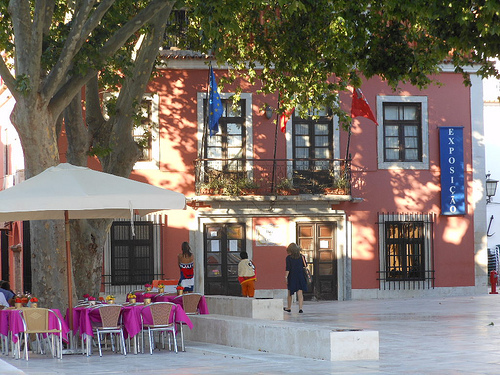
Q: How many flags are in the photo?
A: Three.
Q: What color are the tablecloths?
A: Purple.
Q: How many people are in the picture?
A: Three.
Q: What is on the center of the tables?
A: Flowers.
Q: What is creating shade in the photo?
A: The tree.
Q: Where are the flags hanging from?
A: The balcony.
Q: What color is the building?
A: Red.